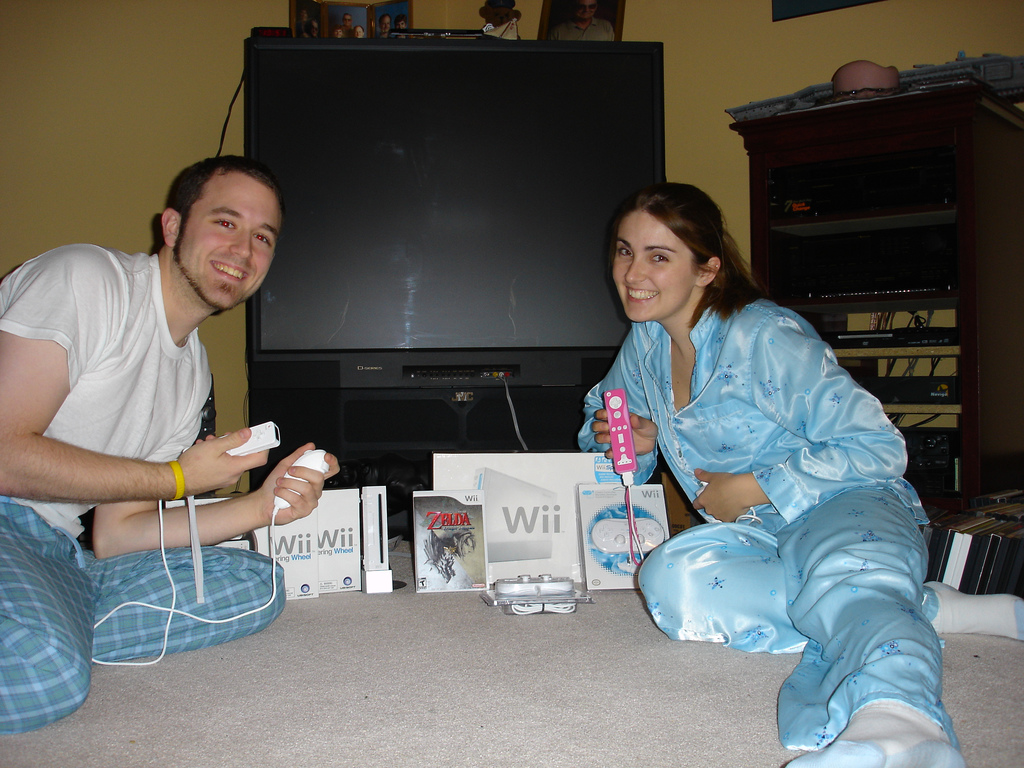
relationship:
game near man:
[407, 484, 492, 597] [3, 157, 342, 744]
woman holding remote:
[526, 161, 978, 731] [594, 385, 654, 492]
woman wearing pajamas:
[526, 161, 978, 731] [566, 319, 948, 729]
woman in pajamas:
[526, 161, 978, 731] [566, 319, 948, 729]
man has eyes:
[3, 129, 359, 722] [213, 210, 277, 252]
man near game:
[3, 157, 342, 744] [407, 484, 492, 597]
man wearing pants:
[3, 129, 359, 722] [2, 504, 309, 733]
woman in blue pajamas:
[526, 161, 978, 731] [566, 319, 948, 729]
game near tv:
[407, 484, 492, 597] [220, 18, 734, 482]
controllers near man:
[488, 467, 685, 634] [3, 157, 342, 744]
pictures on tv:
[282, 1, 642, 54] [220, 18, 734, 482]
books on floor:
[896, 489, 1023, 585] [17, 530, 1021, 763]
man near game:
[3, 129, 359, 722] [407, 484, 492, 597]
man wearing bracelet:
[3, 129, 359, 722] [164, 455, 191, 505]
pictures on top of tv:
[282, 1, 642, 54] [220, 18, 734, 482]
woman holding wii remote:
[526, 161, 978, 731] [594, 385, 654, 492]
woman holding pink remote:
[526, 161, 978, 731] [594, 385, 654, 492]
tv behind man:
[220, 18, 734, 482] [3, 157, 342, 744]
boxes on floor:
[190, 418, 711, 605] [17, 530, 1021, 763]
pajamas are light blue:
[566, 319, 948, 729] [745, 365, 815, 409]